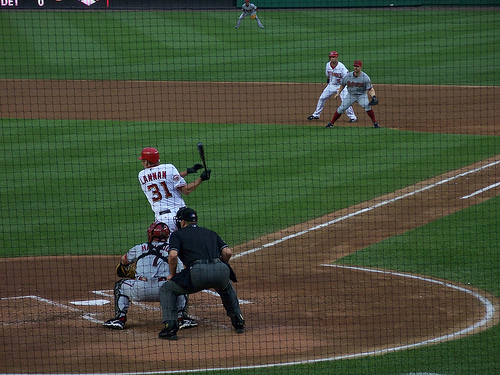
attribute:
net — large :
[2, 0, 498, 373]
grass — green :
[4, 6, 498, 86]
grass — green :
[201, 196, 498, 373]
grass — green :
[4, 118, 498, 256]